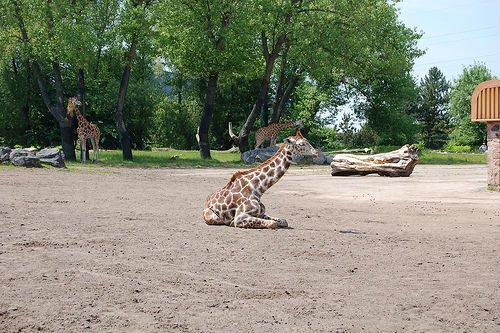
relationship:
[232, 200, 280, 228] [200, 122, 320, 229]
leg of a giraffe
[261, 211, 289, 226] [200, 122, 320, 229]
leg of a giraffe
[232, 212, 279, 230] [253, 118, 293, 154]
leg of a giraffe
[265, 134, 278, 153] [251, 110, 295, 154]
leg of a giraffe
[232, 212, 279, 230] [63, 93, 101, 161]
leg of a giraffe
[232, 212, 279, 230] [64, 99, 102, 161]
leg of a giraffe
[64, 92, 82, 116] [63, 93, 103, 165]
head of a giraffe